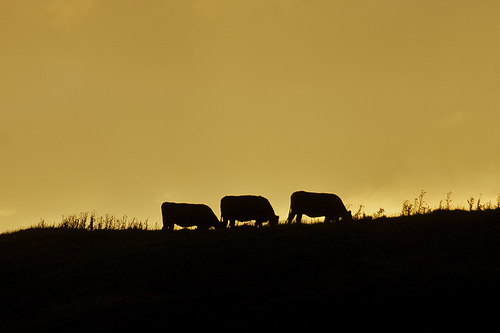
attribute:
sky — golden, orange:
[1, 2, 498, 230]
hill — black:
[1, 209, 498, 332]